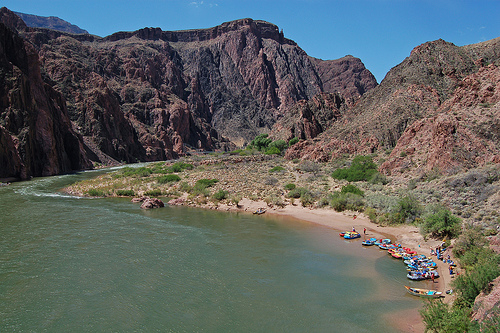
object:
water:
[0, 194, 380, 331]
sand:
[247, 207, 352, 227]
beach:
[61, 149, 478, 331]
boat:
[402, 284, 444, 299]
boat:
[343, 231, 361, 239]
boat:
[339, 230, 351, 236]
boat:
[404, 271, 439, 283]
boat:
[390, 249, 417, 259]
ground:
[71, 156, 498, 263]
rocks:
[54, 32, 209, 153]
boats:
[362, 237, 377, 246]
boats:
[379, 242, 403, 249]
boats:
[406, 269, 438, 280]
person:
[351, 214, 357, 220]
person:
[362, 227, 366, 234]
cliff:
[8, 20, 379, 178]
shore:
[166, 153, 467, 295]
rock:
[140, 195, 167, 210]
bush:
[421, 208, 465, 240]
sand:
[350, 262, 377, 278]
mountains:
[0, 6, 384, 181]